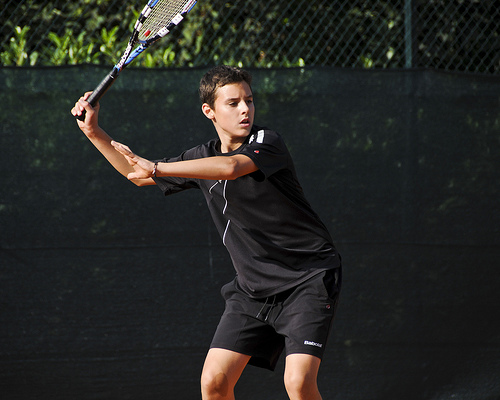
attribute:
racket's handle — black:
[64, 43, 154, 124]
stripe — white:
[257, 121, 267, 148]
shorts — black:
[219, 263, 354, 361]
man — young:
[64, 63, 351, 397]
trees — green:
[54, 15, 266, 63]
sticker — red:
[146, 27, 154, 41]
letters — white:
[273, 320, 336, 350]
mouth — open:
[234, 109, 260, 136]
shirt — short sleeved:
[145, 124, 348, 301]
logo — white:
[300, 337, 325, 350]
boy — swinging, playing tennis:
[70, 62, 342, 399]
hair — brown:
[192, 62, 253, 108]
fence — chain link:
[376, 112, 471, 228]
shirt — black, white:
[153, 128, 336, 300]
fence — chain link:
[4, 6, 466, 396]